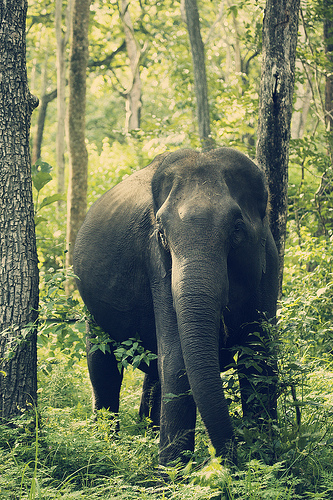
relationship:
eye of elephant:
[223, 202, 259, 243] [45, 159, 314, 479]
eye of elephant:
[153, 213, 161, 220] [78, 154, 280, 350]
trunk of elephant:
[166, 258, 236, 463] [73, 142, 281, 468]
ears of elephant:
[252, 209, 271, 281] [73, 142, 281, 468]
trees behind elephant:
[51, 41, 296, 172] [95, 157, 304, 417]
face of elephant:
[147, 160, 265, 287] [73, 142, 281, 468]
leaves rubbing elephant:
[55, 312, 152, 376] [23, 137, 311, 435]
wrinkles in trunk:
[177, 260, 216, 295] [158, 244, 249, 458]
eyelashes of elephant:
[151, 224, 165, 233] [73, 142, 281, 468]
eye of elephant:
[154, 218, 169, 250] [73, 142, 281, 468]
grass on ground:
[0, 223, 333, 500] [0, 452, 329, 498]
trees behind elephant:
[0, 0, 333, 423] [73, 142, 281, 468]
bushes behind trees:
[279, 160, 332, 411] [1, 2, 331, 141]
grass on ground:
[9, 335, 329, 495] [5, 326, 330, 497]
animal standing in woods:
[71, 148, 281, 473] [1, 1, 322, 495]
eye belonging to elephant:
[154, 218, 169, 250] [73, 142, 281, 468]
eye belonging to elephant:
[228, 214, 249, 243] [73, 142, 281, 468]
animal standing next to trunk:
[60, 148, 329, 392] [1, 128, 44, 246]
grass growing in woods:
[0, 223, 333, 500] [1, 1, 322, 495]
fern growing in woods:
[46, 359, 81, 405] [1, 1, 322, 495]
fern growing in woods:
[230, 458, 303, 497] [1, 1, 322, 495]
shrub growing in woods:
[224, 306, 309, 426] [1, 1, 322, 495]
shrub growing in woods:
[276, 260, 322, 367] [1, 1, 322, 495]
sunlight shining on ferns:
[191, 445, 229, 496] [181, 441, 243, 492]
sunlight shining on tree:
[24, 2, 321, 438] [62, 0, 91, 299]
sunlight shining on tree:
[24, 2, 321, 438] [178, 0, 216, 150]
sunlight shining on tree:
[24, 2, 321, 438] [115, 1, 144, 132]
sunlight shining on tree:
[24, 2, 321, 438] [51, 1, 75, 225]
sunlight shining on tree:
[24, 2, 321, 438] [31, 39, 130, 164]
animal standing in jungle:
[71, 148, 281, 473] [1, 1, 322, 497]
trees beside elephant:
[0, 0, 333, 423] [73, 142, 281, 468]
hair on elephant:
[248, 157, 272, 219] [58, 134, 294, 417]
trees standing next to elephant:
[0, 0, 333, 423] [73, 142, 281, 468]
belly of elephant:
[72, 180, 151, 348] [54, 150, 295, 473]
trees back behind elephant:
[0, 0, 333, 423] [73, 142, 281, 468]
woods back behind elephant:
[283, 0, 331, 305] [73, 142, 281, 468]